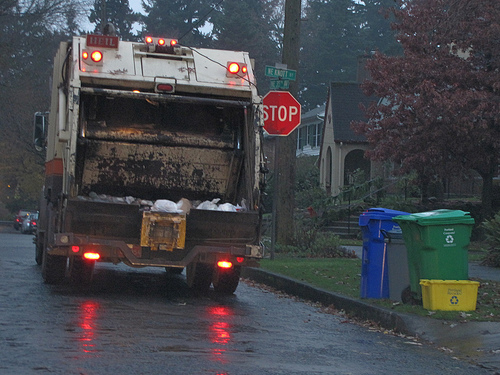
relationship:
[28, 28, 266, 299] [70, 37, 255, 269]
garbage truck has back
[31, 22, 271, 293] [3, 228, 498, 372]
garbage truck on street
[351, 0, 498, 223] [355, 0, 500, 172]
tree with leaves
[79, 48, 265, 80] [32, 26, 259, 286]
lights on truck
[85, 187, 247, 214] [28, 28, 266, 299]
garbage inside garbage truck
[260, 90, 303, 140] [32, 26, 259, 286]
sign beside truck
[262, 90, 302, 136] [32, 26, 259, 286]
sign beside truck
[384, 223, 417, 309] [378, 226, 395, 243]
trash can has handle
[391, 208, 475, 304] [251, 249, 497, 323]
bin on grass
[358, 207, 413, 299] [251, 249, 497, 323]
bin on grass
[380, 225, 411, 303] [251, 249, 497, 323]
trash can on grass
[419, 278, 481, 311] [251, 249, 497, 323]
bin on grass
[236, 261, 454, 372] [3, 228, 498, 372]
grey curb near street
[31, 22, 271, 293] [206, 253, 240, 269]
garbage truck has light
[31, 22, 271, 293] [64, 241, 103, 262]
garbage truck has light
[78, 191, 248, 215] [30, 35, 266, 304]
garbage in back of truck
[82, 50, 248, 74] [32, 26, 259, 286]
lights on truck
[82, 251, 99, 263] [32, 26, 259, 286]
light on truck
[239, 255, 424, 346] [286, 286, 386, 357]
leaves in gutter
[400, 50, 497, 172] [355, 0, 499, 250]
leaves on trees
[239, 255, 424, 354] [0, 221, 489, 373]
leaves on road